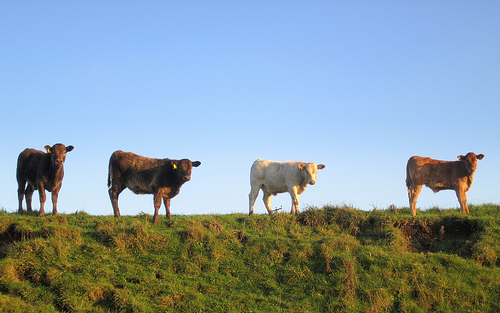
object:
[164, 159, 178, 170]
cow ear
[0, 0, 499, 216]
sky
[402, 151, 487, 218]
cow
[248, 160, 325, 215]
cow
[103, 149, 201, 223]
cow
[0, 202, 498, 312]
hill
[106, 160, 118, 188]
tail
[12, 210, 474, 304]
hill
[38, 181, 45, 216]
leg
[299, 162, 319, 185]
face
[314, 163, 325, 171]
ear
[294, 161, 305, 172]
ear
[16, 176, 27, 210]
leg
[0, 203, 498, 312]
grass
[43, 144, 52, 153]
brown ear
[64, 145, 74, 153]
brown ear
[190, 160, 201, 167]
brown ear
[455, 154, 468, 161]
brown ear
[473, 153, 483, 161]
brown ear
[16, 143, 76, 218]
cow